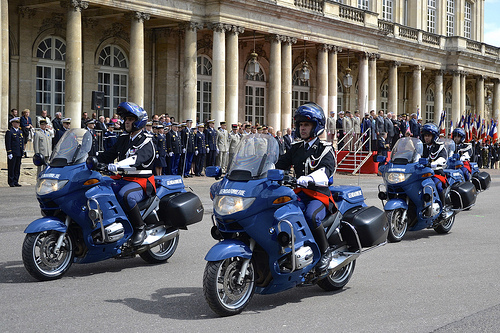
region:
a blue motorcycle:
[198, 156, 378, 316]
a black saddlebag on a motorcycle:
[159, 185, 209, 230]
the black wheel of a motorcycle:
[21, 223, 70, 278]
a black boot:
[310, 220, 332, 273]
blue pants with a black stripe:
[112, 175, 154, 215]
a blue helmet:
[291, 99, 328, 141]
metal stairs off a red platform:
[329, 122, 374, 177]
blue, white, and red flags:
[439, 112, 499, 144]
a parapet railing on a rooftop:
[376, 17, 444, 46]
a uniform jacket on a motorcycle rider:
[272, 139, 340, 192]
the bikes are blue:
[156, 52, 352, 332]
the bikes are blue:
[223, 101, 321, 329]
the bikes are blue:
[209, 153, 284, 315]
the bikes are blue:
[247, 206, 314, 329]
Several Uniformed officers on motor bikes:
[18, 84, 498, 307]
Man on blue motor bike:
[17, 100, 202, 275]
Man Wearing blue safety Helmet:
[111, 90, 155, 146]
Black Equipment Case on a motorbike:
[153, 190, 209, 233]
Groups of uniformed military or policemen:
[156, 120, 228, 175]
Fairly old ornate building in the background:
[0, 0, 499, 112]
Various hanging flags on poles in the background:
[436, 106, 498, 148]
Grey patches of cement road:
[391, 245, 493, 322]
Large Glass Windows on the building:
[33, 27, 68, 119]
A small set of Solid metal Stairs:
[338, 126, 376, 176]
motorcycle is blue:
[199, 146, 381, 314]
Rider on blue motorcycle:
[203, 101, 389, 310]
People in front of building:
[140, 104, 222, 177]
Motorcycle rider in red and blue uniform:
[97, 103, 159, 223]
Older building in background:
[1, 1, 498, 143]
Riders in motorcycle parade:
[23, 101, 498, 308]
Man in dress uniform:
[3, 113, 27, 186]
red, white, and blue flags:
[438, 113, 497, 145]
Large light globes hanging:
[244, 41, 264, 80]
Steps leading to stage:
[332, 124, 379, 175]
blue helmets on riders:
[288, 101, 329, 146]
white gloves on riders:
[294, 165, 341, 195]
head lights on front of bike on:
[206, 187, 256, 219]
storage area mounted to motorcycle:
[341, 195, 395, 249]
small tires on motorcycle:
[201, 238, 259, 315]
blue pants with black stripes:
[118, 180, 150, 218]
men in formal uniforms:
[5, 111, 31, 194]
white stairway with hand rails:
[336, 119, 373, 181]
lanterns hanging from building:
[245, 35, 262, 81]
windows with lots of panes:
[93, 31, 135, 131]